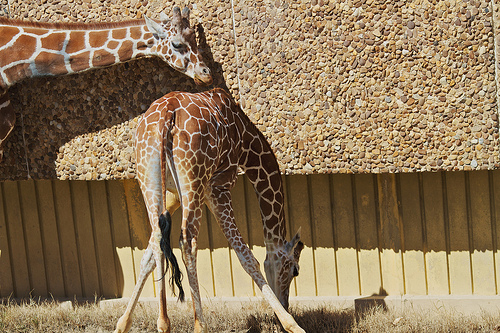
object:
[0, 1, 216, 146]
giraffe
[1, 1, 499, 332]
zoo compound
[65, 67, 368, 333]
giraffe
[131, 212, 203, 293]
hair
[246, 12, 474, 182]
building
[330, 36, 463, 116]
rock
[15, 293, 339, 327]
grass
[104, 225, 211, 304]
head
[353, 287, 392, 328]
shadow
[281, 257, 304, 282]
eye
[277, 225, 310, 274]
ear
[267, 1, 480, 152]
wall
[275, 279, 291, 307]
nose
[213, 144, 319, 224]
neck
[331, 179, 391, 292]
wood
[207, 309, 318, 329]
food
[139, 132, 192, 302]
tail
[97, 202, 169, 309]
leg